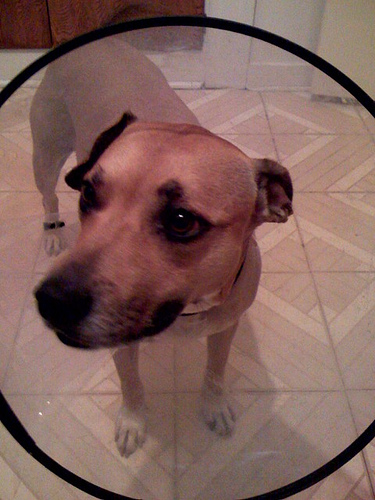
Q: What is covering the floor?
A: Vinyl tiles.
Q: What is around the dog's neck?
A: Cone collar.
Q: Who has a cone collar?
A: The dog.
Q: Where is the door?
A: Behind the dog.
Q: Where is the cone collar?
A: Around the dog's neck.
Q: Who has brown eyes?
A: The dog.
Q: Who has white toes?
A: The dog.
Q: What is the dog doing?
A: Standing.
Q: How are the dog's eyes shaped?
A: Round.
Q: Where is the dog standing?
A: On floor.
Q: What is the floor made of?
A: Tiles.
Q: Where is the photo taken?
A: In a room.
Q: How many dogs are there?
A: 1.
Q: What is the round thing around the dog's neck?
A: A plastic collar.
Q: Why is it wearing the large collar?
A: To prevent biting/licking itself.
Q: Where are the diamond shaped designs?
A: On the floor.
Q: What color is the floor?
A: Gray.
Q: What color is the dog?
A: Brown.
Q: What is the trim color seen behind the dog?
A: White.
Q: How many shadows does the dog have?
A: One.